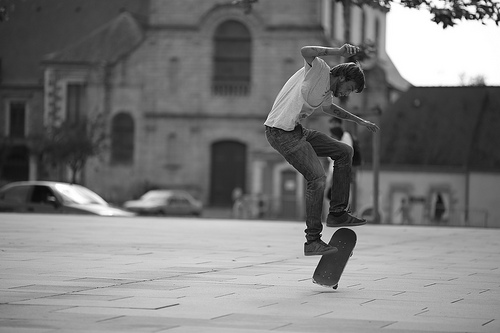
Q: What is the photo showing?
A: It is showing a walkway.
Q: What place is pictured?
A: It is a walkway.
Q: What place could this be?
A: It is a walkway.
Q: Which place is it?
A: It is a walkway.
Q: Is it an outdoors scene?
A: Yes, it is outdoors.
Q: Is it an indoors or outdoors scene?
A: It is outdoors.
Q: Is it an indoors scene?
A: No, it is outdoors.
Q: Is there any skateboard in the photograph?
A: Yes, there is a skateboard.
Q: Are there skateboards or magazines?
A: Yes, there is a skateboard.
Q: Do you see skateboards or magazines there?
A: Yes, there is a skateboard.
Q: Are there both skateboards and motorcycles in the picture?
A: No, there is a skateboard but no motorcycles.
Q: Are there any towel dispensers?
A: No, there are no towel dispensers.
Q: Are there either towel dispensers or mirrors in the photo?
A: No, there are no towel dispensers or mirrors.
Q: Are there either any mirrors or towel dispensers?
A: No, there are no towel dispensers or mirrors.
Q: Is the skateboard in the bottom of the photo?
A: Yes, the skateboard is in the bottom of the image.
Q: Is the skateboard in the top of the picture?
A: No, the skateboard is in the bottom of the image.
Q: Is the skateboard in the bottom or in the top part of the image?
A: The skateboard is in the bottom of the image.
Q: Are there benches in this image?
A: No, there are no benches.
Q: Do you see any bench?
A: No, there are no benches.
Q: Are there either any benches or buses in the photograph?
A: No, there are no benches or buses.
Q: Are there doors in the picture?
A: Yes, there is a door.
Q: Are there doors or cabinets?
A: Yes, there is a door.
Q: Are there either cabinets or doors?
A: Yes, there is a door.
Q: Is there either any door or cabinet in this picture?
A: Yes, there is a door.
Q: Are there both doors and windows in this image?
A: Yes, there are both a door and a window.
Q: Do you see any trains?
A: No, there are no trains.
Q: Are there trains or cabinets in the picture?
A: No, there are no trains or cabinets.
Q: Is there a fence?
A: No, there are no fences.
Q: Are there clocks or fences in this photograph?
A: No, there are no fences or clocks.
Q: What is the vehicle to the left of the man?
A: The vehicle is a car.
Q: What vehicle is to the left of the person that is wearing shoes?
A: The vehicle is a car.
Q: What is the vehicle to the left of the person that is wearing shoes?
A: The vehicle is a car.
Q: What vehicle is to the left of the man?
A: The vehicle is a car.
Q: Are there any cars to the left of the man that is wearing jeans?
A: Yes, there is a car to the left of the man.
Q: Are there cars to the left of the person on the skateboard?
A: Yes, there is a car to the left of the man.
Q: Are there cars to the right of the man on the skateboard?
A: No, the car is to the left of the man.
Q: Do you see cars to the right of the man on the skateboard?
A: No, the car is to the left of the man.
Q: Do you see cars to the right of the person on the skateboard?
A: No, the car is to the left of the man.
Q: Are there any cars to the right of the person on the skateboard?
A: No, the car is to the left of the man.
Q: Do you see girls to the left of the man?
A: No, there is a car to the left of the man.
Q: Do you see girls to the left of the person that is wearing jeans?
A: No, there is a car to the left of the man.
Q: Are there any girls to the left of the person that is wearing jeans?
A: No, there is a car to the left of the man.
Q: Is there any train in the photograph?
A: No, there are no trains.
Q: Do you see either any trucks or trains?
A: No, there are no trains or trucks.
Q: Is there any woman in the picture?
A: No, there are no women.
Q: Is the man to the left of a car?
A: No, the man is to the right of a car.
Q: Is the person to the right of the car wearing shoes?
A: Yes, the man is wearing shoes.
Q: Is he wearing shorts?
A: No, the man is wearing shoes.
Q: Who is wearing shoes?
A: The man is wearing shoes.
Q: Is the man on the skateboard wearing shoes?
A: Yes, the man is wearing shoes.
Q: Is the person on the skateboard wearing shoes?
A: Yes, the man is wearing shoes.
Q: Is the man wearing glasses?
A: No, the man is wearing shoes.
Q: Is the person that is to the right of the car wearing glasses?
A: No, the man is wearing shoes.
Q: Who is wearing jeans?
A: The man is wearing jeans.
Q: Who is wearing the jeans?
A: The man is wearing jeans.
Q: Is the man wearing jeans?
A: Yes, the man is wearing jeans.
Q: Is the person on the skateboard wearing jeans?
A: Yes, the man is wearing jeans.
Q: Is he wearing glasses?
A: No, the man is wearing jeans.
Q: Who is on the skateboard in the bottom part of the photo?
A: The man is on the skateboard.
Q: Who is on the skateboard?
A: The man is on the skateboard.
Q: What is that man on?
A: The man is on the skateboard.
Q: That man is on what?
A: The man is on the skateboard.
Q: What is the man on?
A: The man is on the skateboard.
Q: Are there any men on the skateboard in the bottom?
A: Yes, there is a man on the skateboard.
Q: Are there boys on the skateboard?
A: No, there is a man on the skateboard.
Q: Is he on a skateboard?
A: Yes, the man is on a skateboard.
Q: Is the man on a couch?
A: No, the man is on a skateboard.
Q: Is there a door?
A: Yes, there is a door.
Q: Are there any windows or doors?
A: Yes, there is a door.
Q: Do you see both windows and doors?
A: Yes, there are both a door and a window.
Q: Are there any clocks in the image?
A: No, there are no clocks.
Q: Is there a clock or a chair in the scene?
A: No, there are no clocks or chairs.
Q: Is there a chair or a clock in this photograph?
A: No, there are no clocks or chairs.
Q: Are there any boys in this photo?
A: No, there are no boys.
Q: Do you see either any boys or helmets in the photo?
A: No, there are no boys or helmets.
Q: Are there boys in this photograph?
A: No, there are no boys.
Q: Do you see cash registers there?
A: No, there are no cash registers.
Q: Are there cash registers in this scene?
A: No, there are no cash registers.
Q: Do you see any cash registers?
A: No, there are no cash registers.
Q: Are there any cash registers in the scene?
A: No, there are no cash registers.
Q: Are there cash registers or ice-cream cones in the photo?
A: No, there are no cash registers or ice-cream cones.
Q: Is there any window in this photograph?
A: Yes, there is a window.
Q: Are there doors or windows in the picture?
A: Yes, there is a window.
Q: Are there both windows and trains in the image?
A: No, there is a window but no trains.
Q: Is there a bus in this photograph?
A: No, there are no buses.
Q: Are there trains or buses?
A: No, there are no buses or trains.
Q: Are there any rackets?
A: No, there are no rackets.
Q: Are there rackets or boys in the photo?
A: No, there are no rackets or boys.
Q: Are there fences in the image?
A: No, there are no fences.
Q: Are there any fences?
A: No, there are no fences.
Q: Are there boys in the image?
A: No, there are no boys.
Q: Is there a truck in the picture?
A: No, there are no trucks.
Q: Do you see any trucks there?
A: No, there are no trucks.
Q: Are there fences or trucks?
A: No, there are no trucks or fences.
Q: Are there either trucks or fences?
A: No, there are no trucks or fences.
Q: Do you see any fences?
A: No, there are no fences.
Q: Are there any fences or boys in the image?
A: No, there are no fences or boys.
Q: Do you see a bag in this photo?
A: No, there are no bags.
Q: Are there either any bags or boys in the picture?
A: No, there are no bags or boys.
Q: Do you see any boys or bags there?
A: No, there are no bags or boys.